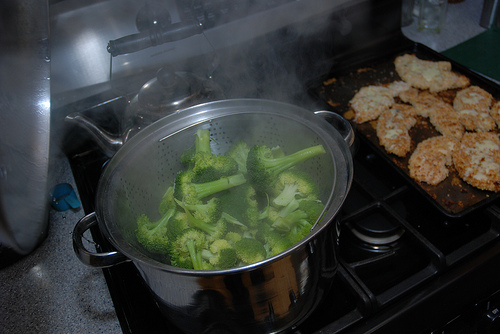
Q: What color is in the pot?
A: Green.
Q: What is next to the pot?
A: A pan.